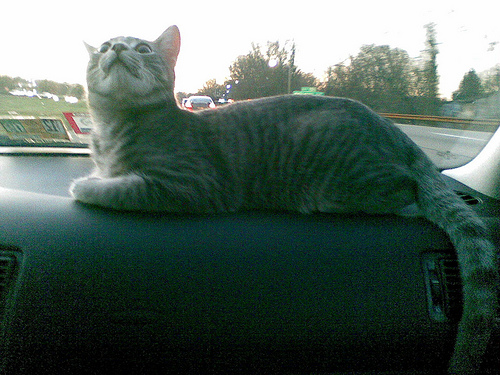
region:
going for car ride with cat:
[0, 0, 496, 372]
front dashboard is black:
[0, 156, 430, 228]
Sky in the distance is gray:
[184, 0, 494, 39]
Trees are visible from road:
[196, 46, 498, 88]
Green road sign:
[287, 85, 329, 97]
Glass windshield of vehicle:
[0, 0, 499, 145]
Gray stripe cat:
[77, 27, 387, 222]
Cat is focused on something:
[94, 41, 153, 56]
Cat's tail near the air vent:
[423, 187, 495, 364]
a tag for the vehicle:
[0, 114, 70, 146]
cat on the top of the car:
[78, 34, 494, 374]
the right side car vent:
[416, 253, 473, 319]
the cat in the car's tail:
[421, 186, 498, 366]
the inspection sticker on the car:
[4, 117, 70, 142]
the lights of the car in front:
[188, 91, 215, 108]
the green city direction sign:
[298, 83, 339, 104]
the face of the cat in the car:
[81, 40, 188, 105]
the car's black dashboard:
[5, 195, 413, 325]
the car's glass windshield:
[1, 7, 496, 168]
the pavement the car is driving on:
[79, 82, 489, 149]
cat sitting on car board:
[74, 25, 497, 373]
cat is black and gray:
[70, 26, 496, 367]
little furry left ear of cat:
[151, 25, 180, 67]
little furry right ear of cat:
[79, 42, 95, 54]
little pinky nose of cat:
[110, 40, 125, 54]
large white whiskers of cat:
[87, 59, 179, 114]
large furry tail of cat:
[417, 180, 497, 370]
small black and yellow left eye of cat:
[133, 40, 153, 54]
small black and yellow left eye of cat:
[100, 40, 112, 56]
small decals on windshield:
[0, 109, 99, 147]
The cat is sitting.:
[66, 38, 478, 225]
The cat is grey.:
[68, 38, 460, 223]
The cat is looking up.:
[70, 24, 478, 232]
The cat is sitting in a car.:
[71, 26, 488, 373]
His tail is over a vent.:
[416, 174, 496, 369]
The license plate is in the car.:
[3, 113, 74, 145]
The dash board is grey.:
[8, 191, 460, 373]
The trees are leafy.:
[214, 39, 439, 108]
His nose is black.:
[104, 38, 129, 51]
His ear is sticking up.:
[148, 21, 182, 61]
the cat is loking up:
[85, 41, 485, 243]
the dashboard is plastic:
[112, 227, 382, 330]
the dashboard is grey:
[129, 235, 336, 326]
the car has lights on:
[182, 92, 223, 112]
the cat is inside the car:
[72, 30, 475, 232]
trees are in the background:
[336, 48, 456, 98]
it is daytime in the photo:
[22, 23, 470, 196]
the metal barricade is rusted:
[422, 112, 473, 130]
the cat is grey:
[80, 64, 492, 251]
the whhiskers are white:
[119, 60, 160, 85]